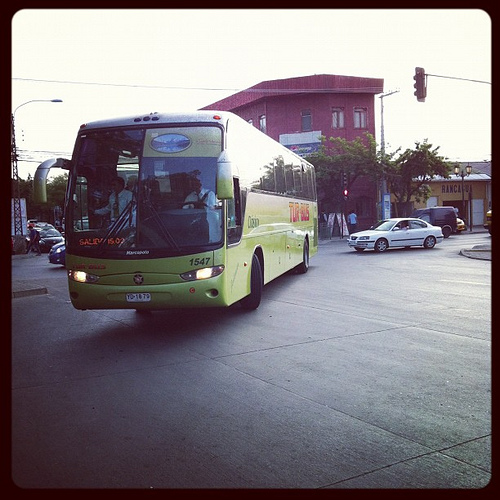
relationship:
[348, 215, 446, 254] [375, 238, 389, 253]
car has wheel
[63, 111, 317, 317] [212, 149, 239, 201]
vehicle has mirror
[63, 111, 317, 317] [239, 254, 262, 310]
vehicle has tire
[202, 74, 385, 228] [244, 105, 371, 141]
building has windows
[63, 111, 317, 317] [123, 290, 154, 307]
bus has licence plate